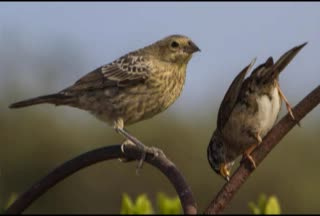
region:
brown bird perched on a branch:
[6, 32, 208, 178]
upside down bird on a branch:
[204, 37, 311, 183]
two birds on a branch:
[8, 26, 318, 203]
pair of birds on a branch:
[8, 28, 316, 213]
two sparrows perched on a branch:
[7, 28, 319, 197]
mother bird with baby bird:
[4, 30, 318, 190]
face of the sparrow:
[153, 28, 201, 72]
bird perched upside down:
[203, 39, 317, 184]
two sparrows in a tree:
[4, 27, 314, 192]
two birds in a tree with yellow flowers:
[6, 29, 312, 214]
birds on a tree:
[19, 25, 299, 179]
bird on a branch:
[15, 32, 203, 158]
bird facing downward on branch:
[205, 42, 305, 176]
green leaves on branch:
[113, 186, 285, 213]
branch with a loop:
[2, 137, 201, 214]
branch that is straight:
[213, 80, 314, 197]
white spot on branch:
[177, 189, 198, 197]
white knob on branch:
[166, 159, 176, 172]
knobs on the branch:
[210, 180, 233, 213]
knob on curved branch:
[163, 162, 179, 176]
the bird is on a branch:
[11, 30, 196, 163]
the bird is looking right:
[12, 28, 196, 160]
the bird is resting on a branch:
[13, 30, 192, 155]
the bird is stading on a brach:
[13, 29, 194, 163]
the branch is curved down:
[12, 145, 199, 211]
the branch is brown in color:
[9, 142, 200, 214]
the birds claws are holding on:
[112, 123, 168, 170]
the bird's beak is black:
[186, 38, 200, 54]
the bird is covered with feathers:
[10, 36, 197, 129]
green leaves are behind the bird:
[122, 189, 180, 211]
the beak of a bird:
[189, 41, 202, 51]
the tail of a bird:
[6, 98, 62, 109]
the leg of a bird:
[119, 130, 156, 160]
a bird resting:
[24, 46, 182, 152]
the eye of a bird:
[169, 41, 182, 48]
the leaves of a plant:
[118, 191, 150, 214]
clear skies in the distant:
[17, 9, 125, 54]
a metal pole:
[169, 164, 202, 211]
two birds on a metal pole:
[19, 19, 290, 179]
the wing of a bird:
[219, 70, 241, 120]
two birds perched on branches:
[6, 17, 315, 200]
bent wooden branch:
[1, 137, 199, 214]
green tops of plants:
[110, 186, 195, 214]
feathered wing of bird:
[64, 49, 149, 97]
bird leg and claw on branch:
[112, 122, 167, 174]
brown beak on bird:
[184, 37, 205, 59]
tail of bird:
[6, 89, 60, 119]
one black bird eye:
[166, 38, 181, 54]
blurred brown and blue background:
[2, 3, 318, 215]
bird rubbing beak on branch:
[200, 40, 317, 190]